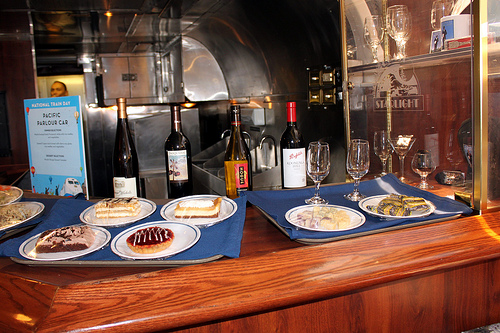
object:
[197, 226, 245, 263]
cloth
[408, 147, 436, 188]
glass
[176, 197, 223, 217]
food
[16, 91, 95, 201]
sign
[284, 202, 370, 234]
plate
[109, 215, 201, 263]
plate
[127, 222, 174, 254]
food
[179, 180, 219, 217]
pastry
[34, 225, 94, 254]
food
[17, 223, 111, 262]
plate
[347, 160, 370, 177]
liquid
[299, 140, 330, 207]
glass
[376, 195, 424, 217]
food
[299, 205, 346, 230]
food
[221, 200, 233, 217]
plate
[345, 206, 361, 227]
plate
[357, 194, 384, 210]
plate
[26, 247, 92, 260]
plate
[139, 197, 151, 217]
plate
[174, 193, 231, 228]
dessert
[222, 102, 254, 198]
bottle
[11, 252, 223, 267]
tray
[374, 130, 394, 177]
glass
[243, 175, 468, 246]
tray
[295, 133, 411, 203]
glasses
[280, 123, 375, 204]
glasses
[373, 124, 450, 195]
glasses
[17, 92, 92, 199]
menu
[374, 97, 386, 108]
letter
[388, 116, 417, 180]
glass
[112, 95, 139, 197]
bottle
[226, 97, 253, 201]
wine bottle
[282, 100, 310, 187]
wine bottle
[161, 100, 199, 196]
wine bottle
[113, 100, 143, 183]
wine bottle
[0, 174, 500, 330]
counter top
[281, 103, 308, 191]
bottle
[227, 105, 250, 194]
bottle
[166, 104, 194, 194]
bottle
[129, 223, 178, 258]
pastry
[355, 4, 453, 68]
glasses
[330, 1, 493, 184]
glass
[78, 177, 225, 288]
cake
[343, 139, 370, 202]
glass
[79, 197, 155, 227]
plate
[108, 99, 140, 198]
wine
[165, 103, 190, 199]
wine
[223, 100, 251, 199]
wine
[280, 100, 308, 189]
wine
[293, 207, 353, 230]
food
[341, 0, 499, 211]
case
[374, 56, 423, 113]
logo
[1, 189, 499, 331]
bar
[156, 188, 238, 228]
plate